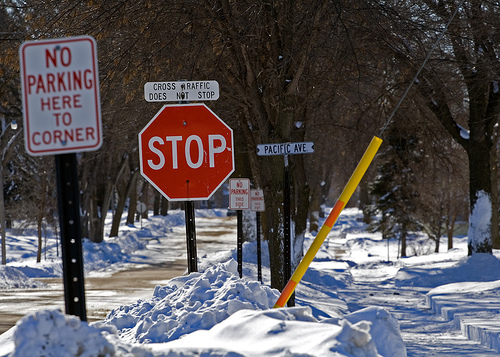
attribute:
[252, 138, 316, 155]
sign — rectangular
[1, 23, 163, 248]
tree — bare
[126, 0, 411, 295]
tree — bare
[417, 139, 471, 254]
tree — bare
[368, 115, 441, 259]
tree — bare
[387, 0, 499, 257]
tree — bare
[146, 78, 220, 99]
sign — white, small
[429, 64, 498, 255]
trunk — old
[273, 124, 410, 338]
pole — bent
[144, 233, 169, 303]
road — frigid, snowy, brown, treacherous, hazardous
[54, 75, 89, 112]
letters — red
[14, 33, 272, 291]
parking signs — communicative, alarming, instructional, explanatory, detailed, meaningful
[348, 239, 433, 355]
sidewalk — snowy, white, powdery, frigid, frosty, thick, frozen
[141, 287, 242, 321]
snow — deep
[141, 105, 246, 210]
sign — white, red, octagonal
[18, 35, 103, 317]
sign — alarming, repetitive, instructional, communicative, advisory, cautionary, helpful, insightful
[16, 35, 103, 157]
sign — red, white, informative, important, alarming, instructive, revealing, descriptive, communicative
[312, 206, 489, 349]
sidewalk — shoveled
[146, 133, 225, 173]
letter — white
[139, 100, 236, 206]
sign — stop sign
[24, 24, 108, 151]
sign — red, white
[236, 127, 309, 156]
sign — white, informative, important, simple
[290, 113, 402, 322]
yellow wire — safe, alarming, secure, fastened, bright, viable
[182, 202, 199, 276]
post — sign post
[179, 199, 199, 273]
pole — black